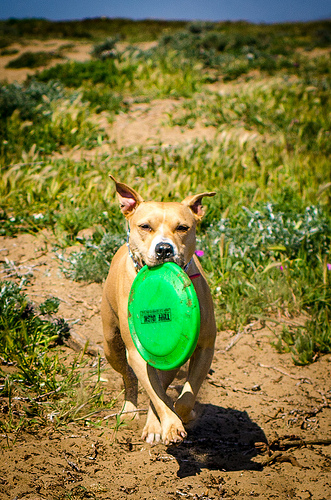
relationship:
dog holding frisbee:
[114, 190, 196, 314] [124, 267, 209, 380]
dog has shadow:
[101, 175, 217, 453] [162, 392, 275, 481]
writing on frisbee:
[139, 307, 170, 323] [125, 260, 200, 372]